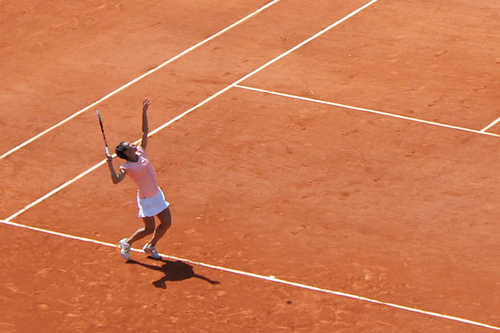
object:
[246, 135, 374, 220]
clay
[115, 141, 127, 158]
hair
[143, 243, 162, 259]
shoe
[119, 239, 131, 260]
shoe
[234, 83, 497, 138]
line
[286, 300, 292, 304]
shadow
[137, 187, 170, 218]
white skirt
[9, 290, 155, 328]
prints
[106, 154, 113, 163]
hand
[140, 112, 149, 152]
arm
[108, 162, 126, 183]
arm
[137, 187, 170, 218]
skirt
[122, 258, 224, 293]
tree trunk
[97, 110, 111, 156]
racket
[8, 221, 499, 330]
line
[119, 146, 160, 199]
shirt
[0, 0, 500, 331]
lines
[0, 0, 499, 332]
tennis court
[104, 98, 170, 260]
girl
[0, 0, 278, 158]
line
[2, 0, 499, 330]
court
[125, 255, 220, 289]
player's shadow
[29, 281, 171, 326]
footprints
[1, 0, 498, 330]
ground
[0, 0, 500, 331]
white lines